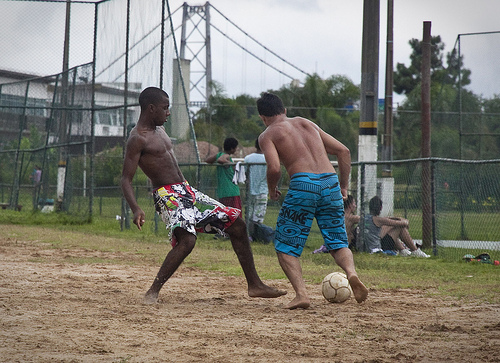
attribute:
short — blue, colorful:
[265, 165, 354, 267]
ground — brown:
[129, 312, 372, 361]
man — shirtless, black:
[87, 56, 223, 304]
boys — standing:
[85, 70, 416, 317]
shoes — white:
[394, 243, 440, 263]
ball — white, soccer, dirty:
[300, 268, 358, 312]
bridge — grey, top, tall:
[34, 6, 343, 115]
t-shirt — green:
[202, 141, 247, 200]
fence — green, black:
[2, 56, 113, 191]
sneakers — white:
[389, 246, 458, 262]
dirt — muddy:
[236, 306, 345, 340]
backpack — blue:
[248, 216, 286, 256]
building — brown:
[13, 63, 149, 164]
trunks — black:
[369, 227, 397, 261]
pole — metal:
[407, 18, 440, 260]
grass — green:
[388, 261, 451, 285]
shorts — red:
[215, 184, 240, 213]